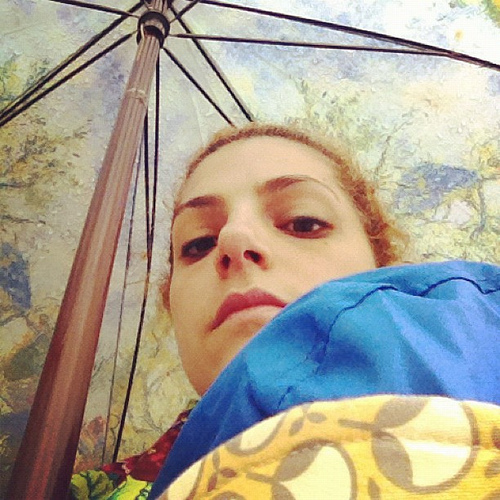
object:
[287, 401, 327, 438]
flower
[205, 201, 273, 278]
nose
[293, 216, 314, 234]
eyeball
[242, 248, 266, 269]
nostril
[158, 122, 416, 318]
hair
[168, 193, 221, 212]
eyebrow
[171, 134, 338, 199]
forehead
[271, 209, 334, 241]
eye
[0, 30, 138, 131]
stem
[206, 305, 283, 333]
lip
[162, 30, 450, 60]
stem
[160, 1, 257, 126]
stem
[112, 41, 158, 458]
stem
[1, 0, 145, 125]
stem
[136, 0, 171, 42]
joint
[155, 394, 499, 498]
blanket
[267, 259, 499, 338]
shoulder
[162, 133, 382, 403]
face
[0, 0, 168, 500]
pole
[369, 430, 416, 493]
leaf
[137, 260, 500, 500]
cloth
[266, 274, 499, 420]
lines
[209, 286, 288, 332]
lipstick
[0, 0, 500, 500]
umbrella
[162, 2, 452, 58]
frame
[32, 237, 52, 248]
drops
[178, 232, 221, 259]
eyes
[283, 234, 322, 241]
lines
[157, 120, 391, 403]
head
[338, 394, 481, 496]
pattern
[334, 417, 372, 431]
stitching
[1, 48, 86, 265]
pattern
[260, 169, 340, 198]
eyebrow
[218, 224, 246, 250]
tip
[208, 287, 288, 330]
lip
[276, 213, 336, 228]
eyelid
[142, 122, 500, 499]
woman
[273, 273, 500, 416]
seam